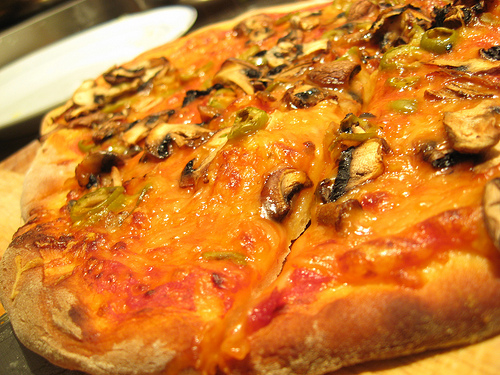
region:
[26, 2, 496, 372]
a cooked pizza on a cutting board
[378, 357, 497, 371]
wooden surface of the cutting board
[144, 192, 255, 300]
yellowed cheese of the pizza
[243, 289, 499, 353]
browned baked crust of the pizza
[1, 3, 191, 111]
wmpty white plate next to the pizza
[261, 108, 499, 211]
mushrooms on the pizza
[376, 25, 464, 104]
peppers on the pizza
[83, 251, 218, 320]
red sauce under the cheese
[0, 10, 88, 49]
steel backsplash of the counter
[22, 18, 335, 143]
a second pizza in the background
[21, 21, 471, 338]
A large pizza on a table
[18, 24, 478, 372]
Mushrooms on the pizza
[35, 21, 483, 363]
the pizza is cooked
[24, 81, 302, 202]
olives on the pizza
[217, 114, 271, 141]
the olives are green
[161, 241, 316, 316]
tomato sauce on the pizza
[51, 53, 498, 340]
the pizza is round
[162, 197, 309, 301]
cheese on the pizza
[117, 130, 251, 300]
the cheese is yellow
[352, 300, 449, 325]
part of the crust does not have cheese.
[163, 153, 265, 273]
some melted cheese on pizza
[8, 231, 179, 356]
thick brown pizza crust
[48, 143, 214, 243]
green peppers on a pizza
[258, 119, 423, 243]
mushrooms on a cheese pizza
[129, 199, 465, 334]
red sause on a pizza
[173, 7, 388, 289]
muli layer of cheese on pizza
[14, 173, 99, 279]
burned piece of crust on a pizza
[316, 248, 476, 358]
crust that got a little burned on a pizza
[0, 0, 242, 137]
a silver bowl on table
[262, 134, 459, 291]
a burnt piece of mushroom on a pizza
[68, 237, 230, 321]
red sauce on the pizza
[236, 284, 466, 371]
brown baked crust of the pizza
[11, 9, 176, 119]
an empty white plate on the counter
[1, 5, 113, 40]
grey metal backsplash of the counter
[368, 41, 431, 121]
green peppers on the pizza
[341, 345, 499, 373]
tan wooden surface of the cutting board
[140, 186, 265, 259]
yellow cheese of the pizza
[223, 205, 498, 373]
crust of the pizza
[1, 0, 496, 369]
pizza on a wooden board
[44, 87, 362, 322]
dark yellow cheese on the pizza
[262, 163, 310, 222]
baked mushrooms on the pizza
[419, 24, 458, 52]
green pepper on the pizza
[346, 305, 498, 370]
wood board under the pizza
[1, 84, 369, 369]
slice of pizza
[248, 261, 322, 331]
red tomato sauce on the pizza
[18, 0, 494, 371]
mushroom, pepper and cheese pizza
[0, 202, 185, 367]
crust on the edge of the pizza